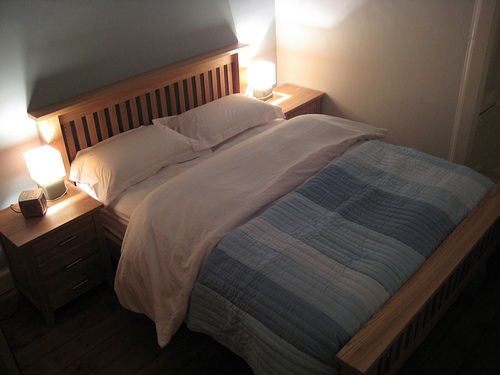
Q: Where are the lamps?
A: On the side of the bed.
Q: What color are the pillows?
A: White.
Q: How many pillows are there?
A: Two.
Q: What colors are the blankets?
A: Blue and white.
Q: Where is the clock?
A: Next to the lamp.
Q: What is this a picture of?
A: A bed and lamps.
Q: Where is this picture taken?
A: In a hotel.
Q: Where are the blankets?
A: On the bed.